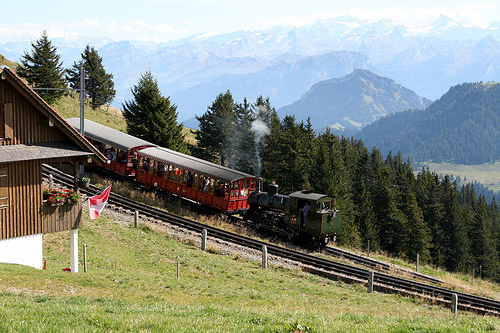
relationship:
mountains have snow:
[0, 15, 500, 165] [13, 12, 500, 48]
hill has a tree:
[0, 53, 500, 333] [16, 29, 68, 106]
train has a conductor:
[57, 117, 261, 214] [299, 203, 311, 226]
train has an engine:
[57, 117, 261, 214] [244, 181, 341, 249]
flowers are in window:
[40, 185, 81, 205] [40, 160, 78, 203]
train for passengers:
[57, 117, 261, 214] [106, 138, 255, 199]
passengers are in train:
[106, 138, 255, 199] [57, 117, 261, 214]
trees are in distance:
[16, 28, 500, 286] [0, 0, 499, 169]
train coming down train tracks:
[57, 117, 261, 214] [42, 162, 499, 315]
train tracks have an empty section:
[42, 162, 499, 315] [326, 240, 500, 317]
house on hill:
[0, 65, 110, 273] [0, 53, 500, 333]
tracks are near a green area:
[42, 162, 499, 315] [0, 177, 500, 332]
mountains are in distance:
[0, 15, 500, 165] [0, 0, 499, 169]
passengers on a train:
[106, 138, 255, 199] [57, 117, 261, 214]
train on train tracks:
[57, 117, 261, 214] [42, 162, 499, 315]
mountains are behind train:
[0, 15, 500, 165] [57, 117, 261, 214]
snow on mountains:
[13, 12, 500, 48] [0, 15, 500, 165]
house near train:
[0, 65, 110, 273] [57, 117, 261, 214]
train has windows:
[57, 117, 261, 214] [101, 144, 261, 199]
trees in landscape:
[16, 28, 500, 286] [2, 3, 498, 332]